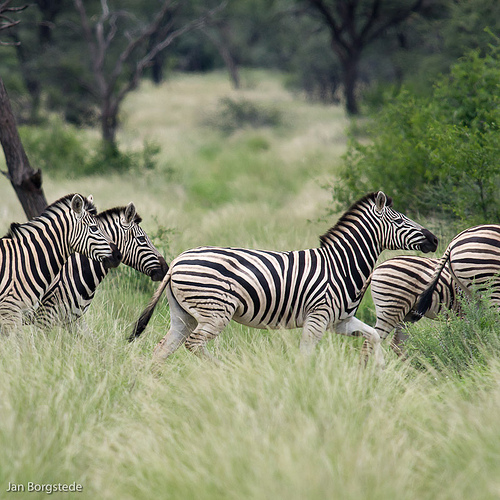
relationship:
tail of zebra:
[395, 225, 468, 330] [436, 195, 498, 325]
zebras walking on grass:
[126, 191, 438, 372] [9, 75, 494, 485]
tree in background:
[75, 67, 138, 177] [5, 7, 493, 212]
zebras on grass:
[1, 193, 123, 337] [17, 341, 483, 498]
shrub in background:
[342, 80, 499, 208] [5, 7, 493, 212]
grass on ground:
[3, 317, 498, 497] [1, 70, 498, 498]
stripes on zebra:
[232, 250, 278, 329] [120, 191, 437, 392]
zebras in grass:
[1, 190, 113, 337] [0, 190, 499, 497]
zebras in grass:
[8, 195, 170, 345] [0, 190, 499, 497]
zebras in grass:
[124, 189, 441, 382] [0, 190, 499, 497]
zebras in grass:
[366, 255, 498, 365] [0, 190, 499, 497]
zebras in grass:
[417, 218, 499, 320] [0, 190, 499, 497]